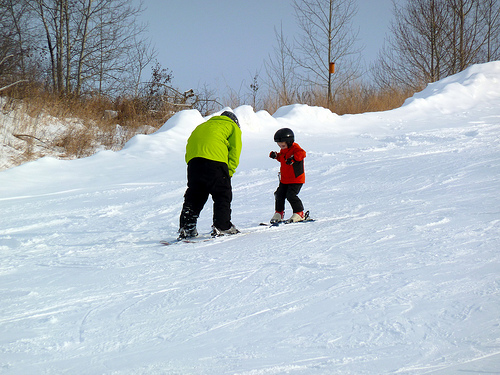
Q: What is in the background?
A: Trees.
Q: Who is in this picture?
A: Snowboarders.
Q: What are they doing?
A: Snowboarding.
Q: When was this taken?
A: Wintertime.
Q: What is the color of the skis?
A: Black.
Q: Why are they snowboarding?
A: For fun.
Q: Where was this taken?
A: Mountainside.